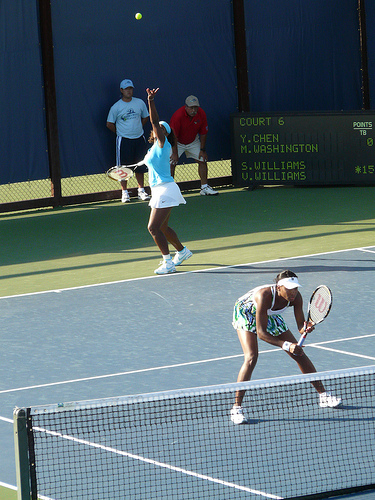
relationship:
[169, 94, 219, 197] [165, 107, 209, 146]
man wearing red shirt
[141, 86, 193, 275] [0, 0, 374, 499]
tennis player on tennis court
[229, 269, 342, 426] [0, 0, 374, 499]
woman on tennis court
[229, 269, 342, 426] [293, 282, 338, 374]
woman playing tennis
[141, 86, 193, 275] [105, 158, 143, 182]
tennis player holding tennis racket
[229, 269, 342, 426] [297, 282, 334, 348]
woman holding tennis racket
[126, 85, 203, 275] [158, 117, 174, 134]
woman wearing visor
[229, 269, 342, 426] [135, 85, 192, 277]
woman playing doubles with woman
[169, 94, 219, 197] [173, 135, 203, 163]
man with white shorts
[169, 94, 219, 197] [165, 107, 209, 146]
man with red shirt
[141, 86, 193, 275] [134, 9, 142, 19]
tennis player ready to serve ball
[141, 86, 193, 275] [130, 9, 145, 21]
tennis player serving ball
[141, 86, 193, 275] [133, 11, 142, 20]
tennis player about to hit ball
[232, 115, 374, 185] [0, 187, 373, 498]
display on tennis court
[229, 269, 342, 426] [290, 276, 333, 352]
woman holding racket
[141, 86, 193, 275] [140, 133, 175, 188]
tennis player wearing shirt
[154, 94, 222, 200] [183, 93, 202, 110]
man wearing cap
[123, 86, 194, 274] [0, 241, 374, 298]
tennis player behind baseline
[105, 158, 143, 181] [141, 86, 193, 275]
tennis racket held by tennis player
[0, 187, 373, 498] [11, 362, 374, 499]
tennis court has net